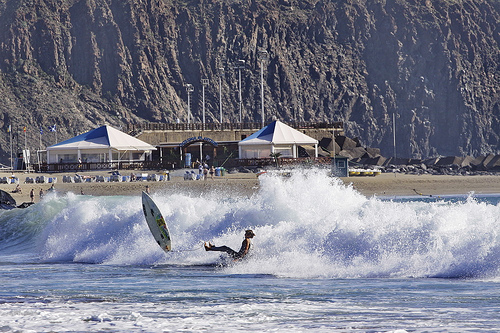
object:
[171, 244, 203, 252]
leg leash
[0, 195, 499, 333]
water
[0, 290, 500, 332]
ocean waves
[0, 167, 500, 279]
ocean waves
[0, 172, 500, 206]
beach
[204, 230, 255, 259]
person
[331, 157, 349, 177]
shed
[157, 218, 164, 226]
stickers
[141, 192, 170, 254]
board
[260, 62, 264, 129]
light posts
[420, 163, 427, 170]
rocks